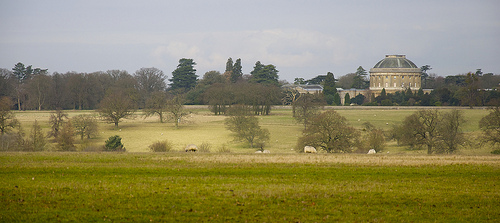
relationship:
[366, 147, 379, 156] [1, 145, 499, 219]
animals eating grass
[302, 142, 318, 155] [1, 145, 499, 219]
animals eating grass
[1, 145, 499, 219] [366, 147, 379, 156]
grass with animals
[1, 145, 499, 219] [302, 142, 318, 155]
grass with animals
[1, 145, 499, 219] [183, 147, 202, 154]
grass with animals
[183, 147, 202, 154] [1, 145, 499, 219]
animals eating grass